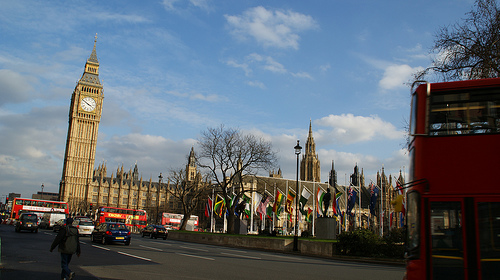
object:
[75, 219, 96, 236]
car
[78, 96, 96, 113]
clock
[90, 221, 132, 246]
car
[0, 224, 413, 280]
road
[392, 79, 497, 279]
bus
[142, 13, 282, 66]
sky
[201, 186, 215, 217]
flag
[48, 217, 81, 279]
person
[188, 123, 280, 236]
tree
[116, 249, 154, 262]
line